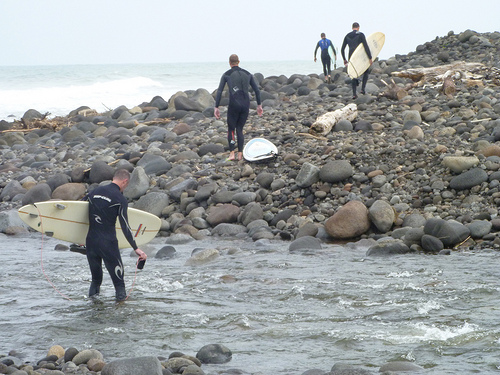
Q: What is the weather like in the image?
A: It is clear.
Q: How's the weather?
A: It is clear.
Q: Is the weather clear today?
A: Yes, it is clear.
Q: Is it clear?
A: Yes, it is clear.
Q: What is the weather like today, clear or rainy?
A: It is clear.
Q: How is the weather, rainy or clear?
A: It is clear.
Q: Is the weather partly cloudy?
A: No, it is clear.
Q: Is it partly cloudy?
A: No, it is clear.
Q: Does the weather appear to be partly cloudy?
A: No, it is clear.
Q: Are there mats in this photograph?
A: No, there are no mats.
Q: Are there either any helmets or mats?
A: No, there are no mats or helmets.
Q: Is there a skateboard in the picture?
A: No, there are no skateboards.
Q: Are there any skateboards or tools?
A: No, there are no skateboards or tools.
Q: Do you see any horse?
A: No, there are no horses.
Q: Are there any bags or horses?
A: No, there are no horses or bags.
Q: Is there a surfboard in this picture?
A: Yes, there is a surfboard.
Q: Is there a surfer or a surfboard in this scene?
A: Yes, there is a surfboard.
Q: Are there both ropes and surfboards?
A: No, there is a surfboard but no ropes.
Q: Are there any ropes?
A: No, there are no ropes.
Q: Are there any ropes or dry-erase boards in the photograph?
A: No, there are no ropes or dry-erase boards.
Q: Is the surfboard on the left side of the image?
A: Yes, the surfboard is on the left of the image.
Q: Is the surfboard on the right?
A: No, the surfboard is on the left of the image.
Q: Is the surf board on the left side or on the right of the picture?
A: The surf board is on the left of the image.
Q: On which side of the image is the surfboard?
A: The surfboard is on the left of the image.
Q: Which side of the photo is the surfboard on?
A: The surfboard is on the left of the image.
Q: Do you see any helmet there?
A: No, there are no helmets.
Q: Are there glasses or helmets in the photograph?
A: No, there are no helmets or glasses.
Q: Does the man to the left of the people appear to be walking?
A: Yes, the man is walking.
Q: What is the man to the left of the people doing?
A: The man is walking.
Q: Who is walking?
A: The man is walking.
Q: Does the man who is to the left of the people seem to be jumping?
A: No, the man is walking.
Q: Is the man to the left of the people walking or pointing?
A: The man is walking.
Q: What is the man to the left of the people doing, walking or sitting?
A: The man is walking.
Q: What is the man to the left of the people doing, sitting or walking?
A: The man is walking.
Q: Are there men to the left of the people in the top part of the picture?
A: Yes, there is a man to the left of the people.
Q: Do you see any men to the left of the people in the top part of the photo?
A: Yes, there is a man to the left of the people.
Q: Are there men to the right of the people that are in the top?
A: No, the man is to the left of the people.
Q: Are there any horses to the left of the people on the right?
A: No, there is a man to the left of the people.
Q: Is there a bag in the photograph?
A: No, there are no bags.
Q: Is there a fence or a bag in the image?
A: No, there are no bags or fences.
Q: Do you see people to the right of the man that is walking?
A: Yes, there are people to the right of the man.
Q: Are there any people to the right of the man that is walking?
A: Yes, there are people to the right of the man.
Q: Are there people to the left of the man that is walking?
A: No, the people are to the right of the man.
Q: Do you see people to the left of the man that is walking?
A: No, the people are to the right of the man.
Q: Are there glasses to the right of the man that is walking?
A: No, there are people to the right of the man.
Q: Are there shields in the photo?
A: No, there are no shields.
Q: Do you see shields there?
A: No, there are no shields.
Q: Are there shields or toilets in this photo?
A: No, there are no shields or toilets.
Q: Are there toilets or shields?
A: No, there are no shields or toilets.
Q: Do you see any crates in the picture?
A: No, there are no crates.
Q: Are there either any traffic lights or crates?
A: No, there are no crates or traffic lights.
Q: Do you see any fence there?
A: No, there are no fences.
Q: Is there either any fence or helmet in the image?
A: No, there are no fences or helmets.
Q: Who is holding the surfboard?
A: The man is holding the surfboard.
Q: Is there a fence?
A: No, there are no fences.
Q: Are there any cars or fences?
A: No, there are no fences or cars.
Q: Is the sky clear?
A: Yes, the sky is clear.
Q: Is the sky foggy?
A: No, the sky is clear.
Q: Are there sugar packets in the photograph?
A: No, there are no sugar packets.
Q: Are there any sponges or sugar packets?
A: No, there are no sugar packets or sponges.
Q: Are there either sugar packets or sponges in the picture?
A: No, there are no sugar packets or sponges.